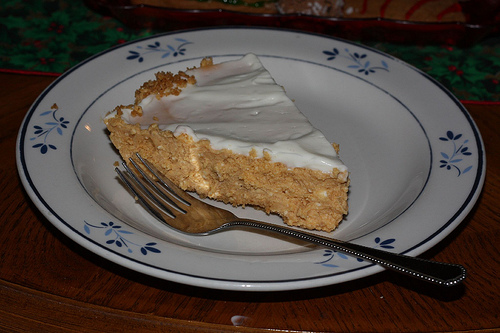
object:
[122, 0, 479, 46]
platter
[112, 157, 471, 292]
fork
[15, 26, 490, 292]
plate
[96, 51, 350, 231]
pie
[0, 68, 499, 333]
table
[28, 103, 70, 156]
flowers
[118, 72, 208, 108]
shell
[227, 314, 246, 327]
smudge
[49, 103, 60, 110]
crumb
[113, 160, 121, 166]
crumb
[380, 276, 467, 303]
shadow